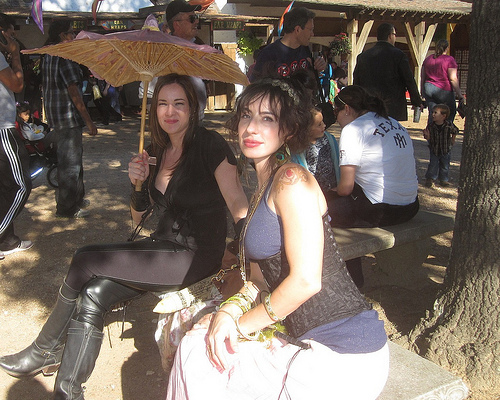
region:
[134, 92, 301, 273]
these are two women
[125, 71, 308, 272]
the two women are staring at the camera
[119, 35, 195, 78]
she is holding an umbrella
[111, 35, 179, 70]
the umbrella is brown in color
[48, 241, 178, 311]
the legs are crossed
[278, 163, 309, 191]
she is having a tatoo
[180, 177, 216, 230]
the blouse is black in color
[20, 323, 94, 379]
the boots are black in color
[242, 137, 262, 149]
the lips are red in color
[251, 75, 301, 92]
floral headband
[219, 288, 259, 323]
lots of bracelets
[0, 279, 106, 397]
pair of black boots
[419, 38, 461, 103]
woman wearing a fuchsia shirt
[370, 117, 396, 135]
black print reading Tex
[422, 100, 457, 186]
small boy wearing a plaid shirt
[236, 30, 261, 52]
lots of green leaves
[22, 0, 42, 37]
purple flag hanging from a pole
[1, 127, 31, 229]
black and white striped pants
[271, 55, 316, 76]
red graphic print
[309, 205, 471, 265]
a stone bench next to a tree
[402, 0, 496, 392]
a brown tree trunk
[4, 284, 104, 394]
black boots on a woman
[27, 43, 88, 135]
a plaid shirt on a man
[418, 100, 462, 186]
a small boy in a plaid shirt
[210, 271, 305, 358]
forearms covered in bracelets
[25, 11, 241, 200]
an umbrella held over a woman's head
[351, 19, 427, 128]
a man in a suit coat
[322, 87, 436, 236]
a woman in a white shirt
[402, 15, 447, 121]
a wooden support post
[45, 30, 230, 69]
this is an umbrella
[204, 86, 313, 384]
this is a lady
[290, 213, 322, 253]
the lady is light skinned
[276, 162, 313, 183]
this is a tattoo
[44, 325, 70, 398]
these are the boots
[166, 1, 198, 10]
this is a cap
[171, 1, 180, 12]
the cap is black in color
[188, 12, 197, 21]
this is a spectacle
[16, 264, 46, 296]
this is the ground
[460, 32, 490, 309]
this is a tree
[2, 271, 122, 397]
woman wearing black boots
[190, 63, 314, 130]
woman wearing a headband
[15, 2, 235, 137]
a straw tan umbrella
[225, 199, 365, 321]
woman wearing a corset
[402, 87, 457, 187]
little boy standing in the shade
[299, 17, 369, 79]
flowers hanging from the ceiling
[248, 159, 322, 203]
a woman with a tattoo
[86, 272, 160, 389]
shadow of the woman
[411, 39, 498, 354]
sun shining on the tree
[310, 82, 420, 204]
woman wearing a white shirt